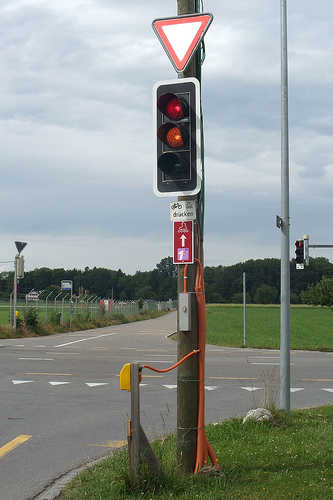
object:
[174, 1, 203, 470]
pole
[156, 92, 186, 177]
signal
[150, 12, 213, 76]
sign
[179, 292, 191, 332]
box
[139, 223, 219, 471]
cord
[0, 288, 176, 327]
fence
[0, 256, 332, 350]
background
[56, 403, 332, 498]
grass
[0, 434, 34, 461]
line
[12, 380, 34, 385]
arrow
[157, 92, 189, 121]
light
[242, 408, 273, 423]
rock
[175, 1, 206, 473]
post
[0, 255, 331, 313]
trees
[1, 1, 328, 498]
outside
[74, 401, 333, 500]
corner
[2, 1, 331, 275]
sky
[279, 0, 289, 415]
pole